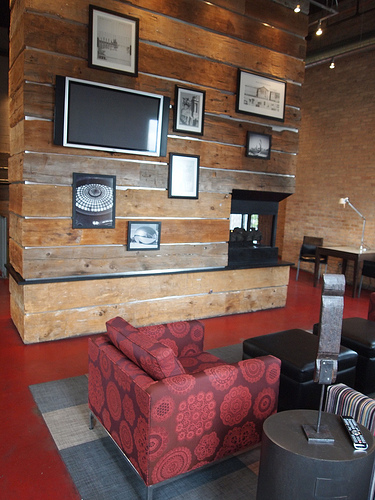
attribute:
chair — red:
[78, 307, 282, 499]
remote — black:
[337, 410, 370, 455]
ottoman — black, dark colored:
[232, 317, 368, 419]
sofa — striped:
[318, 375, 374, 427]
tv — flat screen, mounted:
[47, 68, 176, 165]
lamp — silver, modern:
[296, 270, 352, 450]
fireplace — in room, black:
[222, 189, 296, 274]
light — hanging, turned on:
[311, 14, 327, 40]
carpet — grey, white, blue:
[23, 337, 271, 499]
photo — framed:
[80, 4, 148, 81]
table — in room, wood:
[310, 238, 374, 302]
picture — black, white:
[230, 65, 296, 127]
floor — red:
[1, 253, 369, 500]